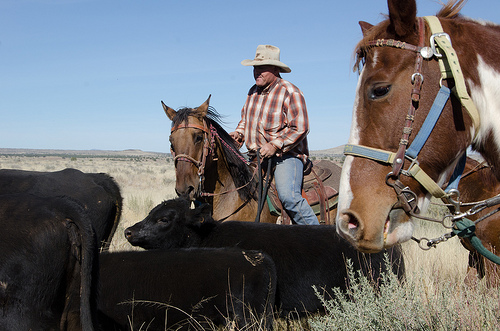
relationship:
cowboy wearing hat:
[226, 44, 321, 226] [222, 40, 337, 87]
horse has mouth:
[335, 0, 498, 286] [315, 199, 440, 255]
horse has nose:
[335, 0, 498, 286] [335, 210, 382, 255]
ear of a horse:
[198, 92, 213, 116] [156, 93, 338, 225]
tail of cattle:
[59, 195, 98, 325] [0, 194, 97, 331]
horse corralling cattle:
[335, 0, 498, 286] [2, 157, 132, 329]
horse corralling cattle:
[160, 93, 406, 286] [2, 157, 132, 329]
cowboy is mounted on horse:
[226, 44, 321, 226] [156, 93, 338, 225]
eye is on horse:
[369, 84, 392, 99] [335, 0, 498, 286]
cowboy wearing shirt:
[226, 44, 321, 226] [232, 81, 308, 160]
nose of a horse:
[333, 204, 367, 245] [335, 0, 498, 286]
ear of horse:
[196, 94, 211, 122] [153, 86, 372, 252]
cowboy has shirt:
[226, 44, 321, 226] [231, 77, 321, 167]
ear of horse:
[161, 100, 177, 121] [156, 93, 338, 225]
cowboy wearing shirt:
[226, 44, 321, 226] [235, 76, 313, 172]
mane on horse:
[163, 102, 243, 152] [156, 93, 338, 225]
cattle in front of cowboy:
[2, 167, 394, 327] [226, 47, 321, 240]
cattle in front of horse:
[2, 167, 394, 327] [160, 93, 406, 286]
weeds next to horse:
[306, 251, 493, 326] [335, 0, 498, 286]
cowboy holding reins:
[226, 44, 321, 226] [235, 129, 278, 204]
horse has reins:
[170, 99, 328, 253] [235, 129, 278, 204]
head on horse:
[333, 13, 463, 251] [335, 0, 498, 286]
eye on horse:
[370, 73, 394, 100] [343, 42, 487, 249]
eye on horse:
[189, 127, 204, 146] [156, 93, 338, 225]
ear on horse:
[384, 0, 418, 31] [335, 0, 498, 286]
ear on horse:
[355, 20, 373, 35] [335, 0, 498, 286]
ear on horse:
[196, 94, 211, 122] [156, 93, 338, 225]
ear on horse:
[157, 98, 174, 117] [156, 93, 338, 225]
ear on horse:
[196, 94, 211, 122] [156, 102, 345, 230]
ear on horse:
[161, 100, 177, 121] [156, 102, 345, 230]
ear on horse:
[358, 20, 374, 37] [322, 0, 497, 272]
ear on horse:
[386, 0, 417, 39] [322, 0, 497, 272]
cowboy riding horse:
[226, 44, 321, 226] [156, 93, 338, 225]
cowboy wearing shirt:
[226, 44, 321, 226] [233, 85, 314, 158]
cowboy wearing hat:
[226, 44, 321, 226] [238, 44, 292, 70]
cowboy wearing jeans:
[226, 44, 321, 226] [270, 155, 330, 232]